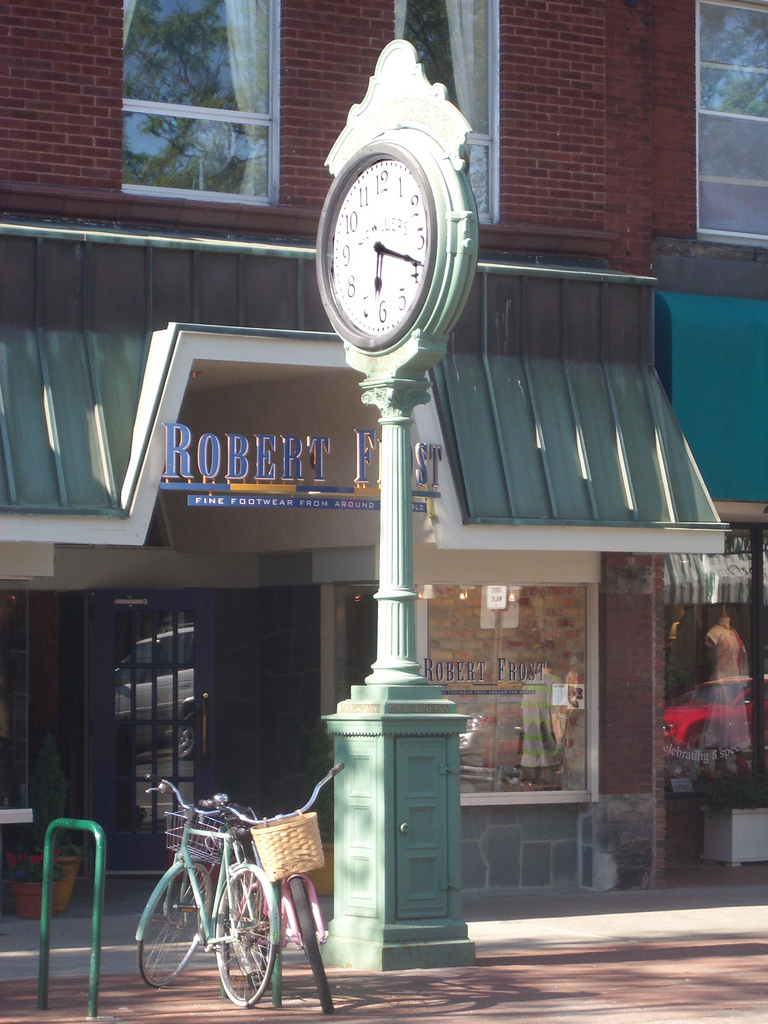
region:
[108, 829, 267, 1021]
green bicycle on street side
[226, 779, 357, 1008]
pink bicycle on street side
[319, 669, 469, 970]
green base of pole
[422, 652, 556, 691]
purple writing on store window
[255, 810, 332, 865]
WICKER BASKET ON BICYCLE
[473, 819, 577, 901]
stone brick wall of building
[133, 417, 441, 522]
purple robert sign on building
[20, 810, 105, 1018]
metal green barrier rail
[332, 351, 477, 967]
Pole is grey color.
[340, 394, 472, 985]
Pole is in sidewalk.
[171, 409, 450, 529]
Letters are blue color.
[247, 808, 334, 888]
basket is brown color.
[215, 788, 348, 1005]
Basket it attached to the bike.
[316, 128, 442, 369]
Clock is white and black color.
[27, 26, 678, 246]
Wall is made of bricks.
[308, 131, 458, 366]
a clock is white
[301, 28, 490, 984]
the clock is in the street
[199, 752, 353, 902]
a basket on front a bike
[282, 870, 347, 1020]
the wheel is black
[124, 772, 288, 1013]
the bike is green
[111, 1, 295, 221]
the window is white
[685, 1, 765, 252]
the window is white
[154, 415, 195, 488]
the R on color blue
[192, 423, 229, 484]
the O on color blue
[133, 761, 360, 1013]
bikes leaning against pole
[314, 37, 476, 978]
green clock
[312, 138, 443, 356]
clock with time reading 6:20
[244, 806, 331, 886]
basket on front of bike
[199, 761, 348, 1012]
pink bike with basket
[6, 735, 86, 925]
plants sitting on ground outside shop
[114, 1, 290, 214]
curtains hanging in window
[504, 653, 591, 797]
people's reflection in window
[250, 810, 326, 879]
wicker basket on the front of a bike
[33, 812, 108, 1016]
curved metal bar painted green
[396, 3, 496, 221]
window on a red brick building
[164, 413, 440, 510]
blue sign that says Robert Frost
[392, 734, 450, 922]
door on the side of a clock post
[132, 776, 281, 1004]
baby blue bike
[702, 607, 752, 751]
white dress in a store window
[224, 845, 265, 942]
a tire on a bike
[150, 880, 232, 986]
a tire on the bike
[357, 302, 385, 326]
a number on the clock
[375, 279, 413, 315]
a number on the clock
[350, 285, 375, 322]
a number on the clock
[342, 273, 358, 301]
a number on the clock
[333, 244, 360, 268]
a number on the clock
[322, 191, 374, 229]
a number on the clock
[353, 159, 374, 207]
a number on the clock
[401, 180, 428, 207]
a number on the clock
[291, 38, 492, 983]
clock on a pole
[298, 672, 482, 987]
green base of clock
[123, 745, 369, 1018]
a pair of bikes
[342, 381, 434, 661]
a green pole for clock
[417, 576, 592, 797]
window in the background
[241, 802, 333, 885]
basket on the bike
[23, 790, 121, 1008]
rail on the side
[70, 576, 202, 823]
door on the building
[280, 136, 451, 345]
face of the clock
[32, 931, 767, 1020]
shadow on the ground